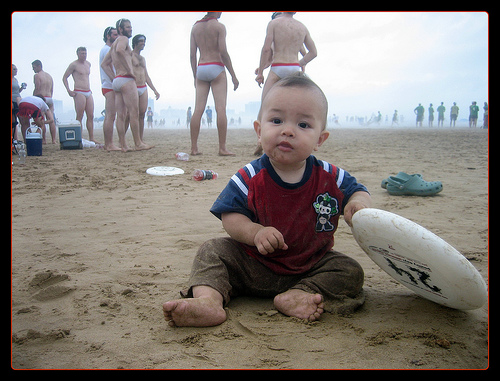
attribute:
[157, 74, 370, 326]
boy — young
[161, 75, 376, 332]
lad — young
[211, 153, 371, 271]
shirt — red, blue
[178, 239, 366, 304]
pants — brown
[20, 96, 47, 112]
shirt — white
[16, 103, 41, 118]
shorts — red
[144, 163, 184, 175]
disc — white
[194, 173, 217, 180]
drink — red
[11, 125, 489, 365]
sand — dark brown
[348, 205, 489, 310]
frisbee — white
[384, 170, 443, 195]
shoe — plastic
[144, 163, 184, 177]
frisbee — white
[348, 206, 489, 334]
frisbee — round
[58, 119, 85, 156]
cooler — green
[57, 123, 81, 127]
lid — white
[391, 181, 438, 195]
shoe — green, plastic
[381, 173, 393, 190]
shoe — green, plastic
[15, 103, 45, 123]
shorts — red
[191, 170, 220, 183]
bottle — tipped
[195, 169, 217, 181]
liquid — red